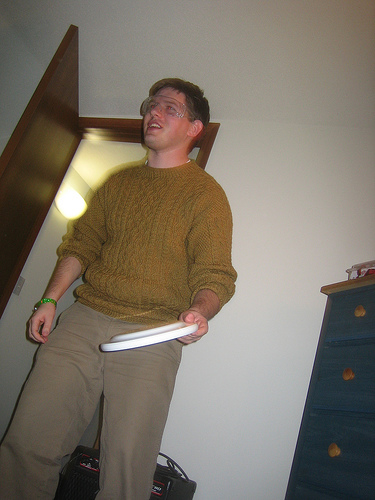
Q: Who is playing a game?
A: A young man.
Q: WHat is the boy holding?
A: Frisbee.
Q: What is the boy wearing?
A: Sweater.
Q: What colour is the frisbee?
A: White.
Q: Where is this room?
A: Living room.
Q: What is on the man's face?
A: Goggles.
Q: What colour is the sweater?
A: Green.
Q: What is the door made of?
A: Wood.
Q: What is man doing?
A: Standing.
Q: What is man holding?
A: Frisbee.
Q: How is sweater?
A: Long sleeve.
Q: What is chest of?
A: Drawers.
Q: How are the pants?
A: Long.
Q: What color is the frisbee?
A: White.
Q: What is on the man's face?
A: Glasses.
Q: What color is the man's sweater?
A: Curry.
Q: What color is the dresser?
A: Blue.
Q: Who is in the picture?
A: A man.